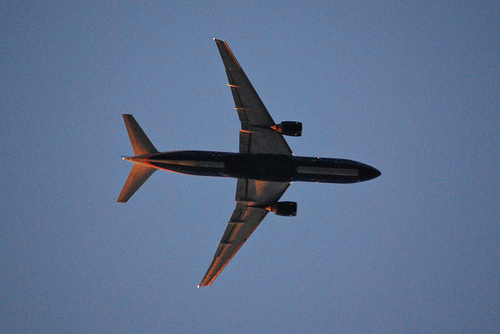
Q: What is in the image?
A: A plane.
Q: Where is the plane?
A: In the sky.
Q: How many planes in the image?
A: One.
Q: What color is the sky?
A: Bluish gray.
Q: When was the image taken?
A: Daytime.